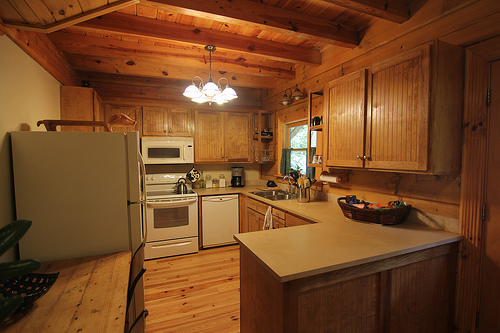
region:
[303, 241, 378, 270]
counter of the kitchen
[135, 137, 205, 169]
microwave in the kitchen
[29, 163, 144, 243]
side of the fridge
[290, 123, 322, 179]
window on the right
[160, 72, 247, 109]
light on the ceiling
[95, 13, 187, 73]
wood on the ceiling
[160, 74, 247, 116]
white lights hanging from ceiling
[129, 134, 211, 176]
white microwave above range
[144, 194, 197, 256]
white range on floor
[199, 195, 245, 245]
white door of dishwasher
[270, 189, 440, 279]
white counter in kitchen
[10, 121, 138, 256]
white fridge and freezer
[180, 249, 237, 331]
floor is light brown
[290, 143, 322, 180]
green curtain on window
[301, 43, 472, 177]
brown cabinets over counter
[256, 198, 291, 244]
towel is beneath sink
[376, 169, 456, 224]
wooden panels of room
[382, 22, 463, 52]
wooden panels of room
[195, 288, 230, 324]
wooden panels of room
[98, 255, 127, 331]
wooden panels of room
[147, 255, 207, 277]
wooden panels of room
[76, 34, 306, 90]
wooden panels of room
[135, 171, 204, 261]
white stove in kitchen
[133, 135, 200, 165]
white microwave above stove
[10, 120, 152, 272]
white refrigerator in kitchen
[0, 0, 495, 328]
kitchen with wooden cabinets and floor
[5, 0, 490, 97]
ceiling with wooden beams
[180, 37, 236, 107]
light hanging from beam in the kitchen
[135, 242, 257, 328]
light colored hardwood floors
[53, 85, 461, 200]
light colored hardwood cabinets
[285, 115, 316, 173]
daylight outside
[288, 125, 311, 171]
greenery visible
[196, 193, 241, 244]
dishwasher next to stove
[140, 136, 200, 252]
microwave above stove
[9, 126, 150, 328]
sideview of the fridge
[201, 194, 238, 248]
white dishwasher in the kitchen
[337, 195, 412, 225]
a basket on the kitchen counter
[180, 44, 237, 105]
chandelier hanging from the ceiling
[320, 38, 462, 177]
wooden overhead cabinets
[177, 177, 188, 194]
tea kettle on the stove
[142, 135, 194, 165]
overhead microwave oven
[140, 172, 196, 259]
white stove in the kitchen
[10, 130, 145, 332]
white refrigerator in the corner of the kitchen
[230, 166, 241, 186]
black food processor